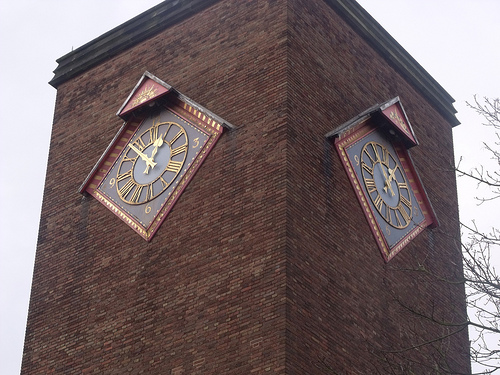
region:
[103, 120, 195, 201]
black and gold face of the clock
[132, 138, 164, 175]
gold metal hands of the clock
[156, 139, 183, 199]
roman numberals on the clock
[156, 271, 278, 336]
brown brick wall of the clock tower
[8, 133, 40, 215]
cloudy white skies over the clock tower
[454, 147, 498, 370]
leafeless tree branches next to the clock tower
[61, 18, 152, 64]
black concrete trim of the clock tower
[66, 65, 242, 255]
a clock on the left side of the tower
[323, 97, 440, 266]
a clock on the right side of the tower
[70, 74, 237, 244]
clock face on a tower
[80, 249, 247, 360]
brick clock tower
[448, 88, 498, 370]
branches of a tree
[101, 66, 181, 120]
an ornamental top above a clock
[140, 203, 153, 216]
the number six on a clock face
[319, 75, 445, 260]
a second clock face on a brick tower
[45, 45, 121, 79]
top detail on a clock tower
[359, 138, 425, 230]
clock face that reads 12:49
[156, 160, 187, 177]
roman numeral 3 on a clock face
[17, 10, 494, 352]
a large brick clock tower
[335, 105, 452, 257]
The clock is a diamond.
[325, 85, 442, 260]
The clock face is black.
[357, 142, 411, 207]
The hands are gold.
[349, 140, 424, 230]
The numbers are gold.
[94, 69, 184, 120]
The triangle is on top of the clock.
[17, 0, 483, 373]
The building is brick.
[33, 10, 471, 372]
The building is red.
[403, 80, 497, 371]
The tree is bare.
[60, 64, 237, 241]
The edge is maroon.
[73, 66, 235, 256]
The edge is gold.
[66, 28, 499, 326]
the wall is brown in colour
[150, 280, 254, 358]
the bricks are rectangular in shape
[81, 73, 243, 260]
the clock is on the wall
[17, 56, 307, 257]
the clock is diamond shaped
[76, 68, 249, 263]
the clock is reddish in colour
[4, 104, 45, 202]
the sky is white in colour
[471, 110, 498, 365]
the tree is leafless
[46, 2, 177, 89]
the roof is black in colour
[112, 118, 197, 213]
the clock is black on the face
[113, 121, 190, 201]
clock indicates time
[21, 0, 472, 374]
brick wall indicates strong structure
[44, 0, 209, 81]
black boarder indicates potential roof and railing around it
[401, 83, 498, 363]
leafless branches indicate winter or fall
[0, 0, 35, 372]
gray skies means sun is behind clouds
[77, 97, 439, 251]
clocks on two sides means people can see time from two different directions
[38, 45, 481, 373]
thin tower may enclose a staircase leading up/down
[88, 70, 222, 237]
ornate design means building is fancy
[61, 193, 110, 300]
stains of brick indicate an aging tower